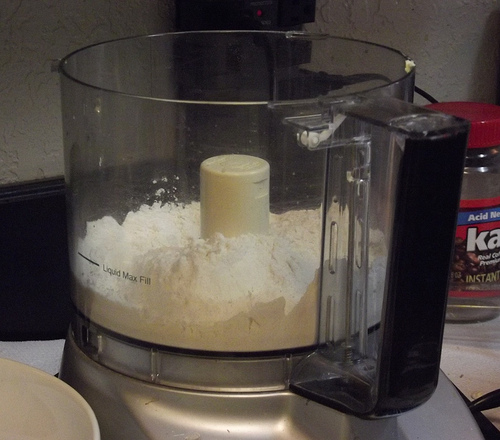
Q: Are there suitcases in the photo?
A: No, there are no suitcases.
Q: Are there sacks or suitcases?
A: No, there are no suitcases or sacks.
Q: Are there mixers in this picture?
A: Yes, there is a mixer.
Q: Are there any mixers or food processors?
A: Yes, there is a mixer.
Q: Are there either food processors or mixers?
A: Yes, there is a mixer.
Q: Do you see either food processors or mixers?
A: Yes, there is a mixer.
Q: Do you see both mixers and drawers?
A: No, there is a mixer but no drawers.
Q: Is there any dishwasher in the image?
A: No, there are no dishwashers.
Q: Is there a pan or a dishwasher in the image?
A: No, there are no dishwashers or pans.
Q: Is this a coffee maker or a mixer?
A: This is a mixer.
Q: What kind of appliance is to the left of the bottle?
A: The appliance is a mixer.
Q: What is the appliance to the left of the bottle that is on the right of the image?
A: The appliance is a mixer.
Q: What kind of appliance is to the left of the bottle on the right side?
A: The appliance is a mixer.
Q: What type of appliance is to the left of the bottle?
A: The appliance is a mixer.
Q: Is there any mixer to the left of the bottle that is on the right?
A: Yes, there is a mixer to the left of the bottle.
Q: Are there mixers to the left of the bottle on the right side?
A: Yes, there is a mixer to the left of the bottle.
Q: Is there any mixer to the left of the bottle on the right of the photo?
A: Yes, there is a mixer to the left of the bottle.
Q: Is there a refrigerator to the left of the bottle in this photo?
A: No, there is a mixer to the left of the bottle.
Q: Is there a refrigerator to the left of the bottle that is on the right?
A: No, there is a mixer to the left of the bottle.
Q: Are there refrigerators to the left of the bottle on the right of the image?
A: No, there is a mixer to the left of the bottle.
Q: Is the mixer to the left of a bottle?
A: Yes, the mixer is to the left of a bottle.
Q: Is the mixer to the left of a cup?
A: No, the mixer is to the left of a bottle.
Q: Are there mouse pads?
A: No, there are no mouse pads.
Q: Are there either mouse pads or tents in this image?
A: No, there are no mouse pads or tents.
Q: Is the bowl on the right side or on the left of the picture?
A: The bowl is on the left of the image.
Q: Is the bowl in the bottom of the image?
A: Yes, the bowl is in the bottom of the image.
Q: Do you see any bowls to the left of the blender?
A: Yes, there is a bowl to the left of the blender.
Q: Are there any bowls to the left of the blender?
A: Yes, there is a bowl to the left of the blender.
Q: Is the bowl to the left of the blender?
A: Yes, the bowl is to the left of the blender.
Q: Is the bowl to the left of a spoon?
A: No, the bowl is to the left of the blender.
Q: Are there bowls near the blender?
A: Yes, there is a bowl near the blender.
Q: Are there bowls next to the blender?
A: Yes, there is a bowl next to the blender.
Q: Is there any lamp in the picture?
A: No, there are no lamps.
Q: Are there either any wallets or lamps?
A: No, there are no lamps or wallets.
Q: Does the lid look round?
A: Yes, the lid is round.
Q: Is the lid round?
A: Yes, the lid is round.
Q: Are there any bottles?
A: Yes, there is a bottle.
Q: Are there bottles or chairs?
A: Yes, there is a bottle.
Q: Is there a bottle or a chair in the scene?
A: Yes, there is a bottle.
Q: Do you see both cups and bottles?
A: No, there is a bottle but no cups.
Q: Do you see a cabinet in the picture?
A: No, there are no cabinets.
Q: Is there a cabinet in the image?
A: No, there are no cabinets.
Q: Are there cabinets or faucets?
A: No, there are no cabinets or faucets.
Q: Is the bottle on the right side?
A: Yes, the bottle is on the right of the image.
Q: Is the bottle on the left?
A: No, the bottle is on the right of the image.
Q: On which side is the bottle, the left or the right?
A: The bottle is on the right of the image.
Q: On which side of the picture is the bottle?
A: The bottle is on the right of the image.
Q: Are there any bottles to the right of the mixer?
A: Yes, there is a bottle to the right of the mixer.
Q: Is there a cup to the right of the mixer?
A: No, there is a bottle to the right of the mixer.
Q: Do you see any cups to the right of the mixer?
A: No, there is a bottle to the right of the mixer.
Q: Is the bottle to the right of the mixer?
A: Yes, the bottle is to the right of the mixer.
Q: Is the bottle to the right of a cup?
A: No, the bottle is to the right of the mixer.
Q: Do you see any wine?
A: No, there is no wine.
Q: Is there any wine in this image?
A: No, there is no wine.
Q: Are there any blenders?
A: Yes, there is a blender.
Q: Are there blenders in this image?
A: Yes, there is a blender.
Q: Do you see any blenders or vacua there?
A: Yes, there is a blender.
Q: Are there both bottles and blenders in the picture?
A: Yes, there are both a blender and a bottle.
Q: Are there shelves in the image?
A: No, there are no shelves.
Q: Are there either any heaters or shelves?
A: No, there are no shelves or heaters.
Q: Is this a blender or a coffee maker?
A: This is a blender.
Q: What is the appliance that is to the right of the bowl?
A: The appliance is a blender.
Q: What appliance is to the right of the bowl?
A: The appliance is a blender.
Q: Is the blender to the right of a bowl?
A: Yes, the blender is to the right of a bowl.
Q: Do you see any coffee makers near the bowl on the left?
A: No, there is a blender near the bowl.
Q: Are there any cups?
A: No, there are no cups.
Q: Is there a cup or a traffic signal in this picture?
A: No, there are no cups or traffic lights.